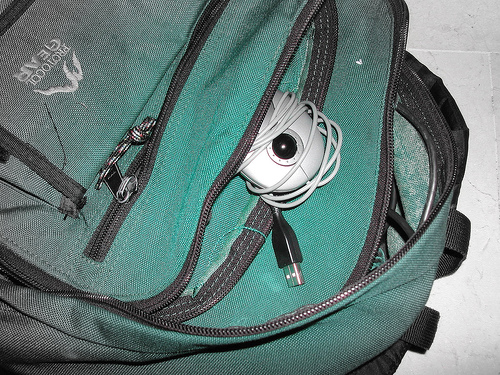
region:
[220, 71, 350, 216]
a mouse in a bag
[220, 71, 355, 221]
the mouse is wrapped with a chord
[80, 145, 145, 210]
the zipper is on the bag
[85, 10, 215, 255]
the zipper is black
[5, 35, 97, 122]
the emblem is white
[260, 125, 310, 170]
the ball on the mouse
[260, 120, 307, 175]
the ball is black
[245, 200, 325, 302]
the end of the mouse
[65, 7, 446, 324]
the bag is aqua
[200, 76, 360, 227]
the mouse is grey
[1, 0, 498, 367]
Worn and used green and black backpack.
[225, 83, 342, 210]
White mouse with corded wrapped around.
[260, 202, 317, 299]
Black USB connector.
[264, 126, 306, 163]
Black built in mouse tracking wheel.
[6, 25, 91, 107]
Protocol Gear brand logo.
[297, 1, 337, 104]
Black zipper with blue stitched pattern.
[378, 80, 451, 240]
Dirt on inside of backpack.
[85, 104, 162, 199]
Multi color rope attached to zipper.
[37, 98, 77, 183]
Frayed string hanging from stitching.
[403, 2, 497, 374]
white tiled ground.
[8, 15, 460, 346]
a green bag with a mouse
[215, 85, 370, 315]
the mouse is white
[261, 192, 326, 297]
this mouse has a black USB connector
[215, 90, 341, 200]
the cord is white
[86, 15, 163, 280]
a black zipper is on the bag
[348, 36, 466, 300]
this bag is open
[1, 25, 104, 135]
the name of the company that makes this bag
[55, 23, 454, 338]
this is a back pack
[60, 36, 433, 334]
this backpack is used to hold goods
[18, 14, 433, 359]
the backpack has three zippers in this shot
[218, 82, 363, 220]
mouse wrapped in a cord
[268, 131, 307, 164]
black ball on the top of the mouse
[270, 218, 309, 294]
top of a black USB cord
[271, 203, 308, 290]
black and silver USB plug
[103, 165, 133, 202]
zipper on the bag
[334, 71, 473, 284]
backpack is unzipped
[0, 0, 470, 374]
green and black backpack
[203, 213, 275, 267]
green string on the bag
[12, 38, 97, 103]
white logo on the bag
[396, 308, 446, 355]
black strap on the bag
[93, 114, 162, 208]
Zipper pull for backpack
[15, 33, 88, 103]
Brand name for backpack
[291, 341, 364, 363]
Part of green backpack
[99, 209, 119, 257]
Part of backpack zipper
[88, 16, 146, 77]
Part of backpack pocket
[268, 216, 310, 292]
USB connector cord for computer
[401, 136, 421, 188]
Interier of green backpack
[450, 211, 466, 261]
Part of backpack strap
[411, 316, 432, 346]
Part of backpack strap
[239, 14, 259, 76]
Part of green backpack